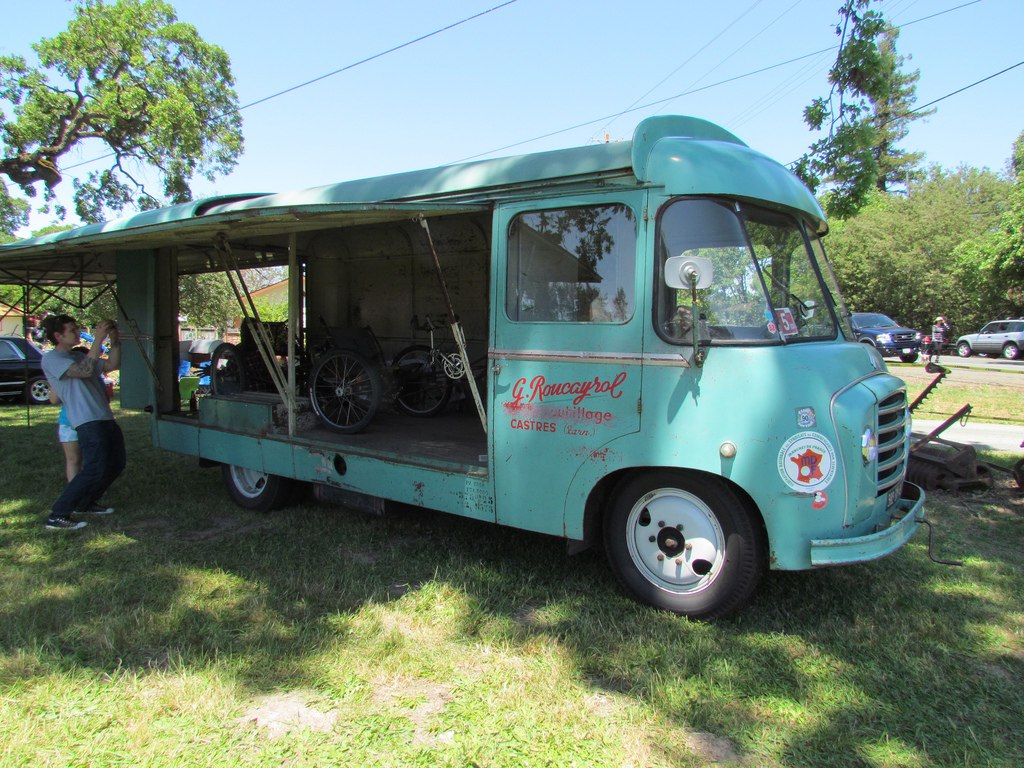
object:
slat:
[877, 388, 905, 410]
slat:
[874, 403, 907, 433]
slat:
[877, 422, 905, 450]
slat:
[876, 441, 906, 468]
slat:
[877, 453, 912, 492]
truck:
[0, 113, 966, 618]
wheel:
[222, 462, 291, 514]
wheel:
[600, 464, 764, 621]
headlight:
[862, 428, 878, 466]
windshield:
[654, 194, 857, 346]